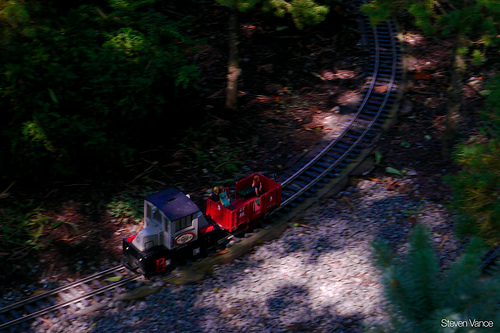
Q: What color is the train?
A: Red and grey.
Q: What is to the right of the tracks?
A: Gravel.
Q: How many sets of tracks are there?
A: 1.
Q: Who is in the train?
A: Children.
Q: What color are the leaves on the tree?
A: Green.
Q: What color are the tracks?
A: Grey.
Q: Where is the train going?
A: Forward.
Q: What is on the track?
A: A train.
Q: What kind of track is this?
A: A train track.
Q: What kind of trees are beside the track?
A: Pine.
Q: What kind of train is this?
A: Toy train.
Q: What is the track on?
A: The ground.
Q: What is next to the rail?
A: Gravel.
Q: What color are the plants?
A: Green.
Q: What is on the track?
A: A train.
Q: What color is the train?
A: Red, blue and silver.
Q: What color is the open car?
A: Red.